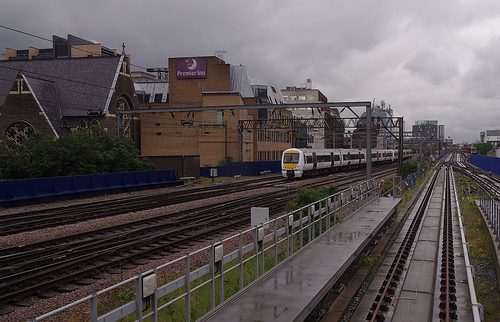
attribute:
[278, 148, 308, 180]
front — yellow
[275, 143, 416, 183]
train — white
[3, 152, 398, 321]
tracks — parallel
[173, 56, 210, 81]
sign — purple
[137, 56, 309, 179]
building — brick, tan, tallest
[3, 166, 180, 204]
barrier — blue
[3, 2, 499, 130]
sky — overcast, gray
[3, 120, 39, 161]
window — decorative, circular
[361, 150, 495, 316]
tracks — straight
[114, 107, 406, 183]
signal — metal, overhead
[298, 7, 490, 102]
clouds — grey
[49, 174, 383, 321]
railing — silver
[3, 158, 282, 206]
wall — blue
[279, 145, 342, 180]
car — yellow, white